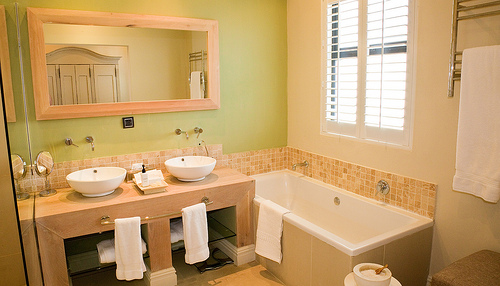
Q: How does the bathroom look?
A: Clean.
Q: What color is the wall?
A: Green.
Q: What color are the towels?
A: White.